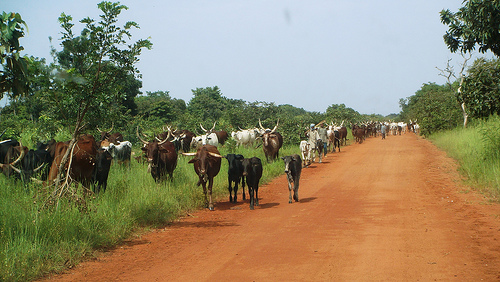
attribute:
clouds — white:
[213, 66, 256, 88]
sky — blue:
[149, 8, 474, 104]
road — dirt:
[87, 135, 496, 273]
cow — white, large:
[199, 118, 219, 145]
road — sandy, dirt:
[28, 124, 497, 279]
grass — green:
[0, 127, 322, 280]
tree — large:
[431, 45, 472, 136]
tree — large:
[396, 76, 460, 139]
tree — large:
[461, 55, 498, 122]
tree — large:
[430, 0, 498, 61]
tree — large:
[0, 0, 157, 214]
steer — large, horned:
[190, 143, 226, 203]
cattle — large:
[8, 115, 420, 211]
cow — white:
[277, 150, 307, 198]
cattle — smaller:
[280, 152, 304, 199]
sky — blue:
[4, 0, 496, 122]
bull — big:
[181, 145, 224, 209]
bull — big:
[132, 119, 177, 184]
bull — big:
[327, 119, 347, 145]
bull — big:
[255, 115, 282, 161]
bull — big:
[198, 119, 227, 147]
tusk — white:
[257, 115, 267, 130]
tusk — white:
[269, 114, 281, 133]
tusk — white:
[208, 117, 217, 134]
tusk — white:
[338, 115, 348, 130]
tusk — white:
[130, 121, 154, 148]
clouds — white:
[374, 28, 450, 73]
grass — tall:
[2, 173, 172, 276]